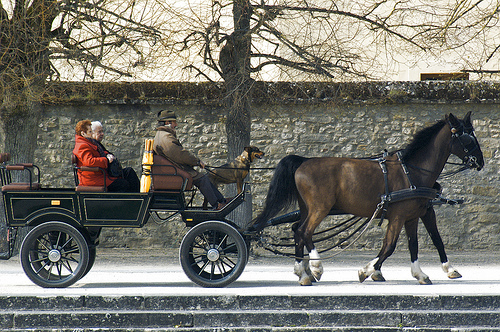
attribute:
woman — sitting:
[47, 106, 140, 201]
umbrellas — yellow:
[138, 149, 190, 193]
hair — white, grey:
[92, 119, 103, 128]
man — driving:
[90, 109, 129, 164]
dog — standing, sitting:
[183, 131, 266, 197]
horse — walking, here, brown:
[254, 101, 482, 278]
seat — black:
[33, 179, 119, 221]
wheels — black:
[163, 221, 252, 291]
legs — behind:
[272, 170, 323, 286]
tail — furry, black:
[248, 119, 306, 224]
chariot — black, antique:
[152, 177, 304, 293]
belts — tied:
[180, 152, 278, 174]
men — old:
[71, 120, 136, 186]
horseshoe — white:
[374, 273, 393, 284]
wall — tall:
[271, 109, 362, 142]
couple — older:
[42, 98, 118, 155]